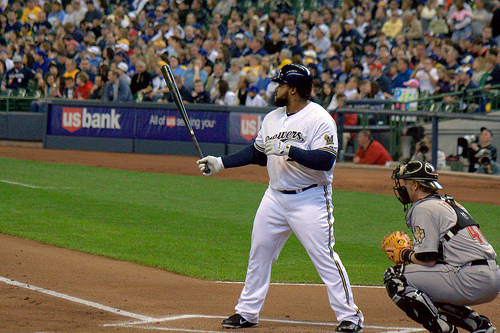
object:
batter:
[196, 63, 365, 333]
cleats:
[221, 313, 260, 328]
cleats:
[335, 320, 363, 332]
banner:
[46, 104, 266, 145]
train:
[385, 145, 492, 316]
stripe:
[321, 185, 361, 326]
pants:
[234, 185, 364, 328]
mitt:
[381, 230, 411, 265]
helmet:
[270, 63, 314, 100]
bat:
[160, 63, 211, 173]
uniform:
[234, 100, 364, 328]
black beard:
[275, 90, 289, 107]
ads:
[43, 99, 267, 156]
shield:
[61, 107, 82, 133]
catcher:
[382, 160, 500, 332]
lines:
[102, 323, 224, 333]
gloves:
[196, 155, 221, 177]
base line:
[0, 276, 154, 322]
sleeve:
[288, 144, 337, 171]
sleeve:
[221, 143, 267, 170]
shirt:
[252, 99, 338, 192]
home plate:
[103, 314, 428, 333]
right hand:
[196, 155, 222, 176]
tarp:
[44, 100, 279, 144]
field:
[0, 139, 498, 333]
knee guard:
[383, 264, 404, 285]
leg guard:
[385, 278, 459, 333]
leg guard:
[431, 299, 498, 333]